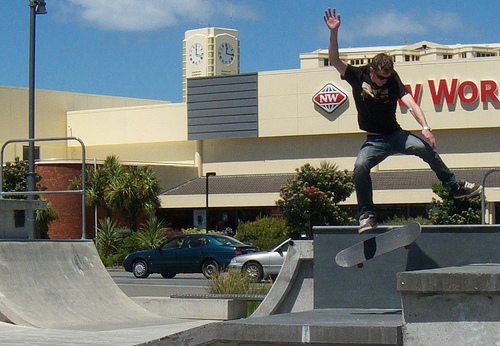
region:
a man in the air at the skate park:
[320, 10, 483, 232]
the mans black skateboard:
[336, 219, 420, 276]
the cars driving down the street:
[112, 223, 291, 285]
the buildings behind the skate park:
[3, 72, 496, 229]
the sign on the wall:
[309, 72, 498, 122]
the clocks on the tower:
[186, 40, 233, 62]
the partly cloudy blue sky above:
[5, 0, 492, 91]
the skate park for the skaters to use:
[1, 233, 495, 344]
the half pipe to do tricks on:
[0, 229, 315, 333]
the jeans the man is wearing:
[346, 130, 454, 212]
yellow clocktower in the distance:
[186, 31, 238, 91]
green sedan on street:
[121, 240, 245, 272]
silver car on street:
[233, 244, 301, 275]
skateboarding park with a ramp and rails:
[3, 140, 495, 342]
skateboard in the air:
[326, 215, 416, 257]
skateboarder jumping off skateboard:
[325, 14, 469, 221]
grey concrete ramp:
[3, 240, 312, 344]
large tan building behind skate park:
[2, 42, 498, 212]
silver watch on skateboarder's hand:
[421, 123, 434, 133]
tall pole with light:
[31, 2, 41, 244]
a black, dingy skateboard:
[333, 220, 419, 265]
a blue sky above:
[115, 45, 150, 65]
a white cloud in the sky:
[40, 0, 250, 30]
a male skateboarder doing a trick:
[310, 5, 480, 230]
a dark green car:
[120, 225, 255, 280]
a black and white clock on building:
[185, 40, 200, 61]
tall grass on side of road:
[209, 265, 264, 291]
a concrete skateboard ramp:
[0, 225, 499, 345]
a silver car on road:
[226, 233, 309, 279]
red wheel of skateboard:
[356, 262, 364, 268]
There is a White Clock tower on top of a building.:
[171, 19, 250, 81]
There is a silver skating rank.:
[5, 234, 138, 344]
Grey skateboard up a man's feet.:
[334, 214, 425, 279]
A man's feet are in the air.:
[353, 171, 485, 237]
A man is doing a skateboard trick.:
[310, 5, 495, 273]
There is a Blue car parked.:
[116, 223, 261, 281]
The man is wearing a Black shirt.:
[352, 76, 402, 138]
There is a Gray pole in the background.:
[9, 32, 60, 137]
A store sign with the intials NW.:
[308, 79, 351, 121]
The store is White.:
[53, 26, 498, 211]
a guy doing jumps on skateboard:
[313, 2, 499, 271]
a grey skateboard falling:
[330, 215, 422, 267]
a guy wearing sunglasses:
[365, 72, 404, 83]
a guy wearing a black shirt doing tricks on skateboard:
[316, 11, 446, 135]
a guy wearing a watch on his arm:
[419, 122, 440, 129]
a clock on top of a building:
[180, 23, 255, 71]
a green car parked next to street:
[123, 230, 255, 285]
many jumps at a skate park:
[0, 224, 499, 338]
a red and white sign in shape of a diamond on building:
[309, 78, 350, 120]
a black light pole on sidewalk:
[200, 161, 225, 241]